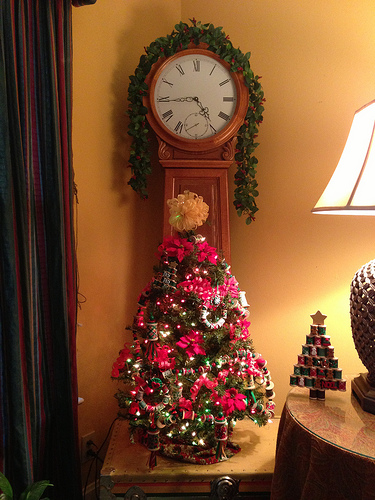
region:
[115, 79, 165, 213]
Leafy garland around mirror.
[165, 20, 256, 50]
Red flowers on green garland.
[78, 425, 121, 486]
2 plugs plugged in to outlet.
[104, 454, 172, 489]
Brown trunk sitting on the floor.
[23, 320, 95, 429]
Striped curtains on windows.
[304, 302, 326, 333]
Star on top of tree.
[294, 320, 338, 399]
Tree made out of spools.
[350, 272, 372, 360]
Lamp sitting on table.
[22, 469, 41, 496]
Green leaves on plant.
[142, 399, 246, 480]
Christmas tree sitting on trunk.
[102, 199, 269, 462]
A small christmas tree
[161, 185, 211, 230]
a bow on top of the tree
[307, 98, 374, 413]
A large brown lamp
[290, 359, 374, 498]
A small table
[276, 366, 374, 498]
A red table cloth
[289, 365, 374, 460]
some glass over the cloth on the table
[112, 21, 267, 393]
A large grandfather clock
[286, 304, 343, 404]
A small christmas tree made of spindles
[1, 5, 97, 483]
some multi colored curtains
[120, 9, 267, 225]
A feux bough of holly on the clock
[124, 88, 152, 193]
red and green holly draping down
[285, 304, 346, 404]
a Christmas tree made of spools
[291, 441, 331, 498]
a red pattern on a tablecloth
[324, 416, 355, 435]
a glass pane on the tabel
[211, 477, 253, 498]
a metal latch on as trunk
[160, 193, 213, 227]
a beige bow on a Christmas tree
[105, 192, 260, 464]
a decorated Christmas tree on a trunk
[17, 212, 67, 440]
striped curtains on the window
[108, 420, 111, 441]
a black electrical cord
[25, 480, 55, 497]
the green leaf of a plant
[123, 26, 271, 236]
The green plant draped over the clock.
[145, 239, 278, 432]
The red poinsettias on the christmas tree.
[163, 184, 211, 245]
The ribbon bow on the top of the tree.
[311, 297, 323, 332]
The star at the top of the tree next to the lamp.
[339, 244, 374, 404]
The bottom part of the lamp.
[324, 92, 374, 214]
The lamp shade on the lamp.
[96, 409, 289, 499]
The beige trunk the Christmas tree is on.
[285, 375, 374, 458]
The glass top table the lamp is on.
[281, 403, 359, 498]
The table cloth to the glass top table.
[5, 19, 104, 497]
The multicolored curtains hanging on the left.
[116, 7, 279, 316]
a grandfather clock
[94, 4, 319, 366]
a grandfather clock decorated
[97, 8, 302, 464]
a grandfather clock behind a tree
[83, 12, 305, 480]
a grandfather clock behind a mini tree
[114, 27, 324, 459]
a grandfather clock behind christmas tree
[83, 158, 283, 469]
a christmas tree decorated in pink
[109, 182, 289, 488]
a tree sitting on a trunk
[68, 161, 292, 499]
a christmas tree on a trunk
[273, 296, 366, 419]
a tree made of spools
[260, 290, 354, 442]
a christmas tree made of spools